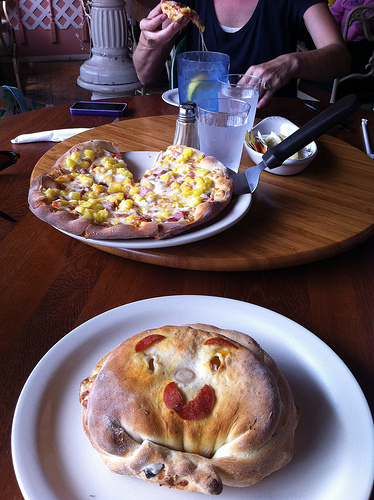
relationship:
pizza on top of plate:
[28, 139, 234, 241] [57, 150, 256, 249]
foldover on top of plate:
[77, 324, 301, 498] [10, 294, 372, 500]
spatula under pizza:
[227, 93, 361, 200] [28, 139, 234, 241]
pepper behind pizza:
[174, 102, 199, 151] [28, 139, 234, 241]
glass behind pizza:
[196, 97, 252, 174] [28, 139, 234, 241]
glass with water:
[196, 97, 252, 174] [195, 120, 246, 175]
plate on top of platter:
[57, 150, 256, 249] [29, 112, 372, 272]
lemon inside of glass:
[186, 72, 214, 102] [175, 51, 231, 116]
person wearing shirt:
[130, 0, 352, 108] [186, 1, 330, 98]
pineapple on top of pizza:
[121, 200, 138, 210] [28, 139, 234, 241]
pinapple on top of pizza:
[190, 197, 201, 205] [28, 139, 234, 241]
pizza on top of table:
[28, 139, 234, 241] [1, 93, 373, 499]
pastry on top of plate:
[77, 324, 301, 498] [10, 294, 372, 500]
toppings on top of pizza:
[53, 150, 210, 223] [28, 139, 234, 241]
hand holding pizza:
[138, 2, 191, 55] [162, 0, 209, 33]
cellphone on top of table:
[70, 100, 130, 116] [1, 93, 373, 499]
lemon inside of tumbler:
[186, 72, 214, 102] [175, 51, 231, 116]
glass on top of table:
[175, 51, 231, 116] [1, 93, 373, 499]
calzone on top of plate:
[77, 324, 301, 498] [10, 294, 372, 500]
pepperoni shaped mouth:
[163, 382, 221, 420] [170, 381, 211, 405]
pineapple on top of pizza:
[106, 181, 124, 193] [28, 139, 234, 241]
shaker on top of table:
[174, 102, 199, 151] [1, 93, 373, 499]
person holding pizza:
[130, 0, 352, 108] [162, 0, 209, 33]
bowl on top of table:
[246, 115, 317, 177] [1, 93, 373, 499]